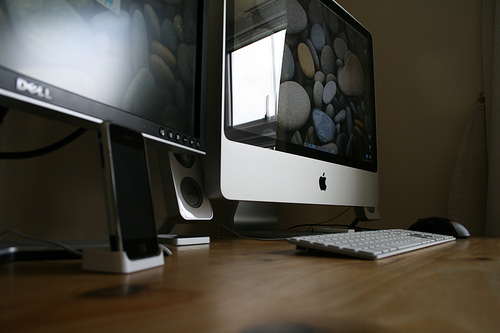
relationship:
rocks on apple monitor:
[282, 49, 347, 153] [221, 0, 382, 208]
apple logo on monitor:
[318, 171, 327, 189] [196, 0, 380, 241]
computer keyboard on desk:
[281, 228, 456, 260] [2, 226, 498, 331]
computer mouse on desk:
[420, 216, 473, 241] [30, 234, 499, 328]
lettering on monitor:
[13, 77, 54, 104] [0, 0, 220, 158]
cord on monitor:
[0, 122, 98, 161] [196, 0, 380, 241]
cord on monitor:
[0, 230, 82, 258] [0, 0, 220, 158]